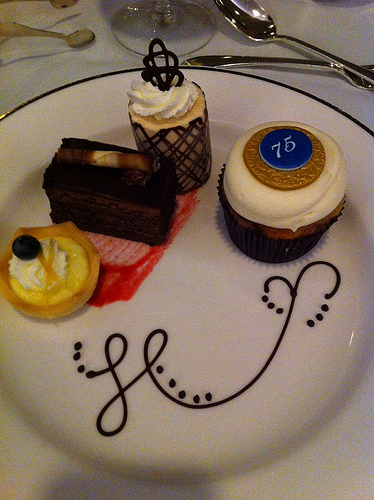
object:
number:
[269, 134, 297, 159]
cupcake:
[214, 118, 350, 265]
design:
[72, 260, 342, 437]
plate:
[1, 64, 374, 499]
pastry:
[125, 36, 212, 196]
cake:
[41, 132, 178, 247]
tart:
[1, 219, 102, 322]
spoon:
[212, 1, 374, 91]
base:
[110, 2, 216, 58]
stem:
[152, 2, 174, 25]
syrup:
[82, 246, 165, 308]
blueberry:
[10, 232, 42, 260]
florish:
[140, 36, 184, 95]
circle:
[258, 126, 313, 171]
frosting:
[221, 121, 349, 231]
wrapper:
[214, 160, 348, 267]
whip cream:
[129, 78, 201, 119]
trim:
[1, 73, 120, 120]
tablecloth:
[0, 0, 374, 137]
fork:
[179, 50, 373, 92]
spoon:
[2, 20, 96, 54]